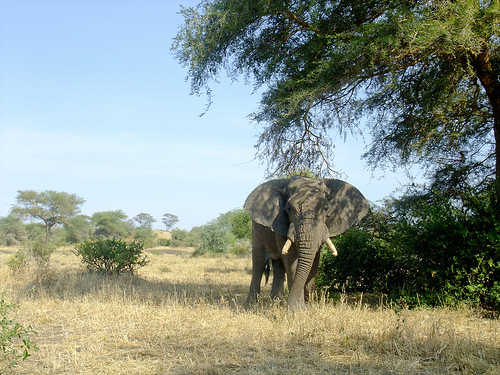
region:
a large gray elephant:
[231, 167, 363, 302]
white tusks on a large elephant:
[272, 233, 363, 272]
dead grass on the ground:
[56, 300, 497, 370]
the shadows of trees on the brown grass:
[194, 328, 498, 360]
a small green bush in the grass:
[78, 236, 142, 276]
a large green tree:
[166, 1, 490, 146]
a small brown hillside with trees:
[106, 220, 208, 249]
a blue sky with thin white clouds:
[30, 103, 212, 183]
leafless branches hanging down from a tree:
[270, 126, 338, 173]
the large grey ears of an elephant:
[248, 186, 370, 231]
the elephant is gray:
[218, 139, 388, 344]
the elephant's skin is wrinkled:
[216, 151, 361, 331]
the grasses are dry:
[78, 268, 285, 365]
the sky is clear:
[5, 30, 283, 192]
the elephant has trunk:
[242, 171, 362, 331]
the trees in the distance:
[5, 126, 235, 261]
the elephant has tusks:
[225, 111, 417, 346]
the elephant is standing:
[237, 143, 332, 321]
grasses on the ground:
[47, 227, 266, 367]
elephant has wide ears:
[211, 169, 451, 313]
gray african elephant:
[231, 166, 353, 306]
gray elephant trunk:
[279, 216, 332, 311]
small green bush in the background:
[61, 216, 181, 289]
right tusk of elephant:
[273, 218, 302, 271]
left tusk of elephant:
[326, 227, 343, 265]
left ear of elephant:
[232, 161, 291, 238]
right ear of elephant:
[317, 161, 381, 237]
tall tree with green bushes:
[179, 18, 497, 150]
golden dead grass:
[35, 262, 402, 360]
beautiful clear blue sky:
[10, 22, 228, 174]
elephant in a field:
[236, 163, 381, 320]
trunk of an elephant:
[292, 233, 325, 325]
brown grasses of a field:
[60, 299, 218, 367]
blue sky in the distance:
[7, 14, 152, 94]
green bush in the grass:
[75, 235, 152, 278]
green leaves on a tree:
[167, 0, 497, 140]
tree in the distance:
[5, 181, 91, 241]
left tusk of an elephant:
[320, 237, 346, 256]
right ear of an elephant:
[240, 178, 285, 234]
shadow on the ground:
[88, 270, 244, 311]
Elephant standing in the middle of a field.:
[228, 157, 368, 301]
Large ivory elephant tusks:
[268, 226, 352, 266]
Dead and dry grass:
[90, 285, 258, 371]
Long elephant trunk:
[287, 225, 314, 332]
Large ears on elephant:
[242, 162, 377, 239]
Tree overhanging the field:
[174, 10, 479, 157]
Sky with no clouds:
[20, 13, 108, 123]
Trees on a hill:
[127, 200, 196, 241]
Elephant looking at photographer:
[238, 159, 398, 266]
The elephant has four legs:
[233, 255, 330, 337]